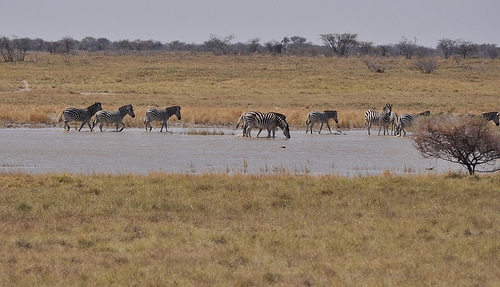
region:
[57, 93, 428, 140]
zebras in the water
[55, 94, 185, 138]
three zebras running in water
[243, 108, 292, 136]
zebra drinkging from water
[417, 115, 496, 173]
bush growing beside water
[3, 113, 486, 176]
water zebras are wading in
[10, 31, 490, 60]
line of trees on horizon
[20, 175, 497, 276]
dry grass in front of water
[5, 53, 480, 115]
dry grass behind water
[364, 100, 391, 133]
zebra looking towards camera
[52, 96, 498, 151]
ten zebras in a herd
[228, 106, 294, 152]
the zebra is drinking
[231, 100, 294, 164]
the zebra is in the water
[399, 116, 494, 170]
the bush is brown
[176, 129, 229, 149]
the grass is growing in the water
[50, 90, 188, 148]
the zebras are walking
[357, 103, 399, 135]
the zebra is standing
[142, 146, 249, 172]
the water is dark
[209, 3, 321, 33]
the sky is gray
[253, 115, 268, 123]
the zebra has stripes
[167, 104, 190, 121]
the zebra has a head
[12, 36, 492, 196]
a herd of zebras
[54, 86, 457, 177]
zebras at a watering hole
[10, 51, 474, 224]
these zebras are on the African planes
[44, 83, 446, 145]
there are eight zebras in this shot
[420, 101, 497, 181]
a tree near the wate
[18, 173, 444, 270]
this grass is scorched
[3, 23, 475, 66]
a skyline for trees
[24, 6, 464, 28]
a hazy day over the plains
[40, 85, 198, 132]
three zebras in the water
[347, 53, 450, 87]
bushes on the plain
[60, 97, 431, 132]
Zebras in the water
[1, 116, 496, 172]
A body of water by the field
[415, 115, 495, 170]
A small tree by the water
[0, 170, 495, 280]
A field near the zebra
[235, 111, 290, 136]
The zebra is drinking the water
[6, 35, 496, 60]
Trees in the distance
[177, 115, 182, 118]
The nose of the zebra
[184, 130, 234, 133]
Grass in the water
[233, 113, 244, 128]
The tail of the zebra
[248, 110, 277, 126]
The zebra has black and white stripes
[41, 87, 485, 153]
zebras in a watering hole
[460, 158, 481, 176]
trunk of a tree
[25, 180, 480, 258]
brown grass on a plain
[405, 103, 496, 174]
tree in the grass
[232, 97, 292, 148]
zebra drinking water in the wild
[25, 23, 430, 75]
trees along the horizon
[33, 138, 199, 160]
water where zebras are drinking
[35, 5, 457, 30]
blue hazy sky in the distance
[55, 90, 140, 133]
zebras running in the water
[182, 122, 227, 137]
patch of grass in water